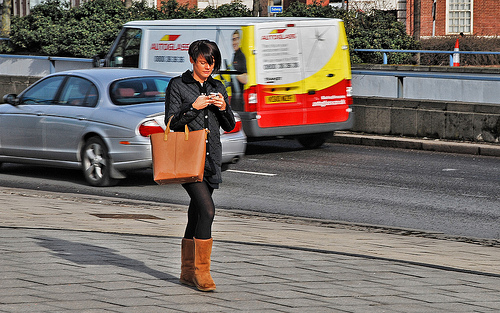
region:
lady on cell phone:
[152, 30, 265, 298]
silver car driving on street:
[4, 63, 254, 195]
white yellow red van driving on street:
[96, 11, 361, 153]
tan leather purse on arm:
[131, 109, 218, 186]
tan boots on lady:
[175, 229, 225, 296]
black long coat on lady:
[169, 68, 241, 188]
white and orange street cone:
[441, 33, 468, 69]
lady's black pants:
[169, 173, 229, 240]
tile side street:
[252, 258, 324, 305]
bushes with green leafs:
[366, 19, 412, 57]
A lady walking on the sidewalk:
[148, 37, 238, 292]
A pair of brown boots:
[176, 237, 217, 290]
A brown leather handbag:
[145, 111, 209, 189]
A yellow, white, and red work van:
[97, 17, 356, 151]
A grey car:
[3, 67, 248, 189]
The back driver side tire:
[73, 132, 113, 187]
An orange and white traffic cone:
[448, 37, 461, 65]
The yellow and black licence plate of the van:
[264, 92, 296, 104]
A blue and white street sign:
[264, 4, 286, 13]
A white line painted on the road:
[227, 168, 277, 177]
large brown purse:
[149, 113, 206, 181]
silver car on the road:
[0, 66, 247, 189]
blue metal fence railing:
[353, 46, 490, 63]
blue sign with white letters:
[270, 4, 283, 11]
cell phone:
[208, 91, 218, 100]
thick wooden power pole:
[410, 0, 421, 62]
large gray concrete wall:
[345, 99, 496, 142]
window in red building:
[445, 0, 472, 33]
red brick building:
[405, 0, 497, 37]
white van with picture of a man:
[95, 17, 355, 145]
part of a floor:
[253, 258, 282, 295]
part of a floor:
[284, 255, 311, 280]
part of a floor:
[254, 228, 316, 285]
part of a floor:
[190, 270, 215, 292]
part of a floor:
[253, 251, 298, 300]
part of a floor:
[280, 228, 319, 259]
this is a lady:
[151, 25, 239, 282]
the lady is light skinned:
[196, 95, 213, 103]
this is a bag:
[146, 126, 211, 183]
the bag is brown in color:
[159, 153, 189, 167]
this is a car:
[34, 60, 141, 178]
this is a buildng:
[422, 9, 498, 35]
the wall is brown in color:
[476, 2, 493, 33]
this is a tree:
[66, 2, 111, 44]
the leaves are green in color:
[80, 0, 130, 40]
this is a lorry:
[255, 38, 338, 117]